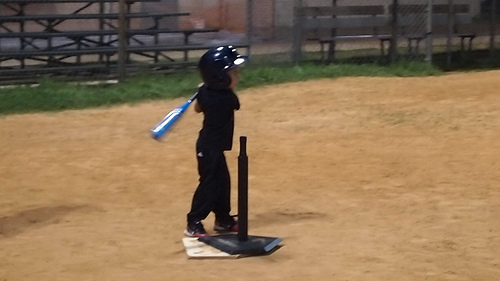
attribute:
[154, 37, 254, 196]
boy — playing, swinging, small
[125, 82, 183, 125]
bat — blue, black, small, held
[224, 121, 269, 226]
tee — black, here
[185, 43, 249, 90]
helmet — black, shiny, worn, dark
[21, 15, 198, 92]
bleachers — empty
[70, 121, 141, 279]
ground — brown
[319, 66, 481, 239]
dirt — brown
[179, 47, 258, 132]
child — playing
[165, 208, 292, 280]
plate — home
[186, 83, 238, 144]
shirt — black, worn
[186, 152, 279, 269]
pants — black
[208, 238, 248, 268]
base — white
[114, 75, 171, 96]
grass — green, stripped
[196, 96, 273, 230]
kid — playing, batting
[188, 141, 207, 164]
triangle — white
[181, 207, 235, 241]
shoes — black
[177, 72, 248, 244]
attire — black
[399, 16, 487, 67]
benches — wood